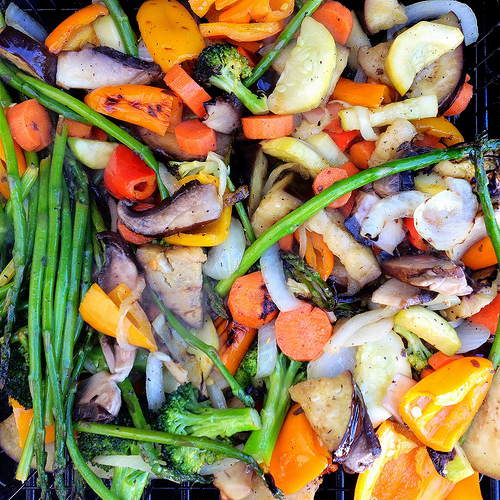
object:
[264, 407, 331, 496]
fruit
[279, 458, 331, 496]
edge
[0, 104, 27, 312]
vegetables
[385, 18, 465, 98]
squash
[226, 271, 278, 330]
carrot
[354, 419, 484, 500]
vegetables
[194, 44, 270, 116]
broccoli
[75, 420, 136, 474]
broccoli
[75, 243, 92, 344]
asparagus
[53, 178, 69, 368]
asparagus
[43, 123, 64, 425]
asparagus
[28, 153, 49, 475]
asparagus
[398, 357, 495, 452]
pepper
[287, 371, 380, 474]
food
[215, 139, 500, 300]
food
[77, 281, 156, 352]
food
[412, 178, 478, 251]
food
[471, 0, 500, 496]
side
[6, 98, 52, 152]
food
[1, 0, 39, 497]
side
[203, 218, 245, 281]
food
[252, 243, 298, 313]
middle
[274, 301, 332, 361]
carrot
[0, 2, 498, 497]
mix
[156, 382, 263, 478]
vegetable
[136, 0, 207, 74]
vegetable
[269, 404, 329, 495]
peppers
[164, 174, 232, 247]
peppers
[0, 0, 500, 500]
stir fry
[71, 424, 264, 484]
bean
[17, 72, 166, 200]
bean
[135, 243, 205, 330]
meat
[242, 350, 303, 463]
broccoli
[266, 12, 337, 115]
not lemon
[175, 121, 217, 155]
carrot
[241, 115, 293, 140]
carrot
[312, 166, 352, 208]
carrot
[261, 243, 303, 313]
onion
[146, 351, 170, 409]
onion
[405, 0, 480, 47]
onion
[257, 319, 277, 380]
onion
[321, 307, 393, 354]
onion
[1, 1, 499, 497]
rack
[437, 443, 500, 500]
corner